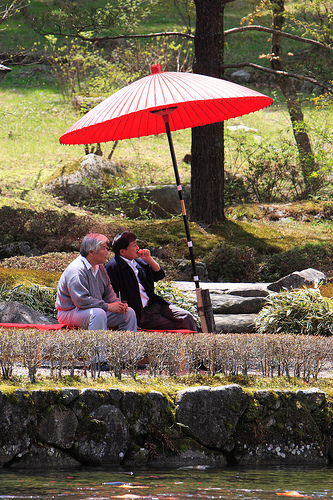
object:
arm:
[68, 275, 108, 308]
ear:
[88, 248, 93, 256]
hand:
[138, 247, 152, 266]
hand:
[105, 300, 124, 315]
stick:
[161, 114, 200, 289]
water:
[0, 471, 333, 498]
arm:
[137, 259, 166, 283]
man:
[107, 229, 199, 333]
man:
[55, 231, 138, 332]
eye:
[101, 244, 106, 253]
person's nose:
[103, 248, 107, 257]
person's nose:
[134, 245, 139, 251]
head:
[79, 231, 111, 262]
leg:
[106, 304, 138, 334]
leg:
[162, 303, 198, 333]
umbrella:
[59, 63, 273, 290]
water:
[226, 199, 317, 220]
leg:
[65, 305, 109, 333]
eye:
[133, 243, 136, 247]